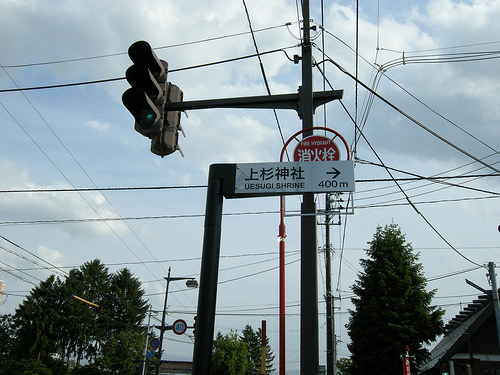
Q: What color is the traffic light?
A: Green.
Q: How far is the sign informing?
A: 400 meters.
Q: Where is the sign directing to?
A: Uesugi Shrine.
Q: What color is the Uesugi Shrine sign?
A: White.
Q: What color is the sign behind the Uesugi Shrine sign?
A: Red.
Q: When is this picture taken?
A: Day time.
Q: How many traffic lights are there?
A: Two.